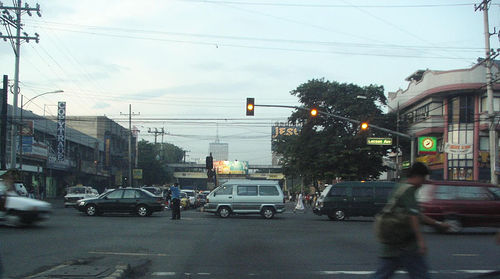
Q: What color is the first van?
A: Silver.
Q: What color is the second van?
A: Black.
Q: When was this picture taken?
A: During the day.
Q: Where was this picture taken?
A: A busy city street.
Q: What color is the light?
A: Yellow.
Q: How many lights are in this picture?
A: Three.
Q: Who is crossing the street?
A: A man.